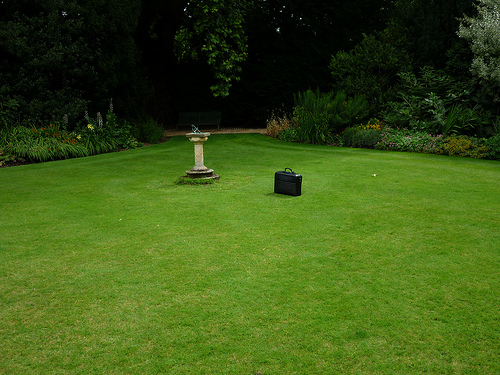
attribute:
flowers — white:
[55, 116, 103, 145]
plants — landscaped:
[265, 2, 499, 159]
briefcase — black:
[266, 166, 311, 207]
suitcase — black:
[268, 162, 304, 204]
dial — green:
[185, 122, 205, 136]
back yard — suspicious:
[96, 133, 404, 311]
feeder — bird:
[180, 122, 213, 171]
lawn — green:
[12, 158, 464, 371]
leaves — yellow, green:
[387, 128, 469, 155]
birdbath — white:
[180, 89, 240, 211]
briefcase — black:
[267, 164, 310, 203]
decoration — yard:
[179, 130, 220, 183]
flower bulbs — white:
[73, 115, 101, 147]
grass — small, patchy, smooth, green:
[2, 132, 498, 372]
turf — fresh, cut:
[340, 204, 454, 284]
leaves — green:
[201, 20, 232, 60]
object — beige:
[272, 165, 302, 195]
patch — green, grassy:
[385, 217, 430, 258]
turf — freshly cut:
[12, 148, 487, 369]